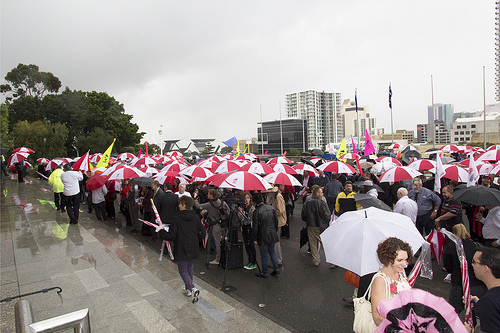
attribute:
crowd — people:
[75, 143, 461, 265]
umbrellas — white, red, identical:
[139, 149, 341, 188]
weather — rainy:
[70, 4, 474, 165]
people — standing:
[89, 119, 496, 293]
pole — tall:
[386, 87, 399, 135]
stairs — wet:
[28, 294, 105, 331]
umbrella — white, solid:
[325, 197, 432, 268]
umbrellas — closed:
[454, 209, 482, 280]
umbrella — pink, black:
[377, 274, 455, 333]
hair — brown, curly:
[381, 244, 407, 255]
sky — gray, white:
[30, 8, 499, 158]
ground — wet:
[24, 199, 209, 332]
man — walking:
[64, 165, 90, 231]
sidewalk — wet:
[5, 173, 134, 307]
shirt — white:
[59, 172, 91, 196]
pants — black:
[62, 196, 84, 224]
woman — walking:
[161, 187, 219, 287]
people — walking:
[4, 151, 105, 224]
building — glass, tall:
[258, 130, 305, 158]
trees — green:
[2, 91, 131, 162]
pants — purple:
[165, 254, 200, 295]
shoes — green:
[242, 261, 257, 271]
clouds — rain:
[73, 11, 360, 107]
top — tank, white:
[376, 280, 407, 302]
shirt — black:
[467, 289, 493, 310]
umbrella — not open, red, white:
[454, 256, 492, 319]